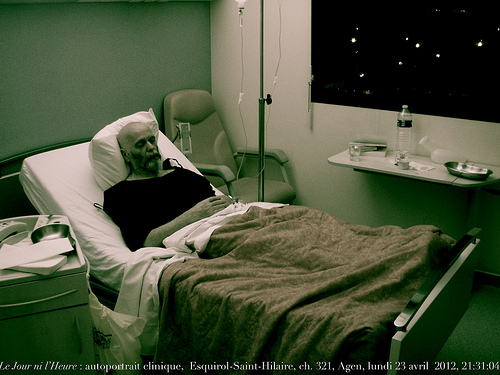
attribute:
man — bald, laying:
[104, 122, 233, 253]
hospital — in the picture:
[1, 1, 499, 375]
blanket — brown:
[113, 202, 461, 375]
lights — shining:
[350, 8, 499, 95]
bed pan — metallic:
[31, 223, 77, 256]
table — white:
[1, 215, 98, 374]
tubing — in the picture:
[235, 1, 282, 202]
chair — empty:
[163, 89, 295, 205]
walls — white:
[0, 0, 499, 275]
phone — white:
[0, 219, 29, 251]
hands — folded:
[199, 195, 228, 218]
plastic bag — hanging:
[89, 289, 148, 374]